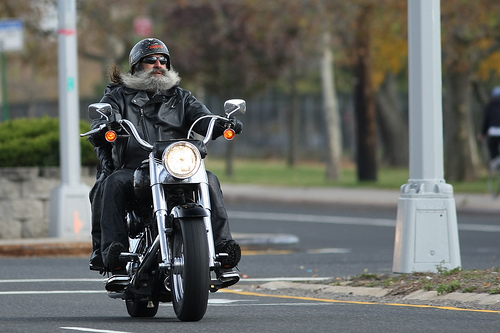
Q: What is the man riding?
A: A motor.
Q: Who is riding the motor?
A: A man.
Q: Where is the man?
A: Riding a motor.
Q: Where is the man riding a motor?
A: On the road.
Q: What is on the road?
A: Man riding a motor.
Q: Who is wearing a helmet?
A: Man riding a motor.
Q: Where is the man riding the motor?
A: On the road.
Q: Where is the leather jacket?
A: On the man riding a motor.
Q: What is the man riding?
A: A motorcycle.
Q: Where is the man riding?
A: On highway.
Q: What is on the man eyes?
A: Sunglasses.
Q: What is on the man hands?
A: Gloves.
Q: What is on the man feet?
A: Boots.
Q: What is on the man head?
A: A helmet.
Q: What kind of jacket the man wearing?
A: Leather jacket.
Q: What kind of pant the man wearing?
A: Leather pants.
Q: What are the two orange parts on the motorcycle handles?
A: Two lights.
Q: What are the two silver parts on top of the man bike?
A: Two mirrors.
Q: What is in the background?
A: Trees.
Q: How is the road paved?
A: With asphalt.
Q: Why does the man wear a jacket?
A: For warmth and protection.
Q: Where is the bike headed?
A: Towards the viewer.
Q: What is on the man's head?
A: A helmet.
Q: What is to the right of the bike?
A: A pole.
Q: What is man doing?
A: Riding motorcycle.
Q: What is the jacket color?
A: Black.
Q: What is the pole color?
A: Grey.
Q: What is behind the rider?
A: Brick wall.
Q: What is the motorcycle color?
A: Black and silver.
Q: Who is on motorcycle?
A: A man.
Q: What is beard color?
A: Grey.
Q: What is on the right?
A: Light post.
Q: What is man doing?
A: Riding bike.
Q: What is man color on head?
A: Black.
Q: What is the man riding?
A: A motorcycle.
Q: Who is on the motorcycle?
A: A man and a passenger.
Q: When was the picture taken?
A: During the day.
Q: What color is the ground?
A: Black.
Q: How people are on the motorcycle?
A: Two.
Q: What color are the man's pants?
A: Black.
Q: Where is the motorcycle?
A: On the street.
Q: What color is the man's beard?
A: Gray.